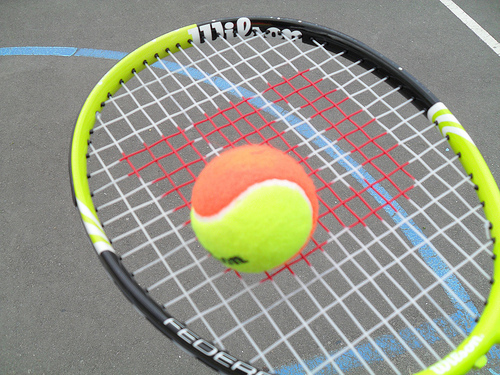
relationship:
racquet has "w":
[71, 17, 496, 371] [125, 70, 419, 289]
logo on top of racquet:
[125, 70, 419, 289] [71, 17, 496, 371]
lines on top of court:
[3, 45, 497, 368] [5, 5, 493, 368]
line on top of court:
[442, 5, 498, 57] [5, 5, 493, 368]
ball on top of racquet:
[190, 144, 321, 276] [71, 17, 496, 371]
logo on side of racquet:
[125, 70, 419, 289] [71, 17, 496, 371]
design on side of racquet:
[66, 200, 117, 255] [71, 17, 496, 371]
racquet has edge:
[71, 17, 496, 371] [32, 28, 193, 254]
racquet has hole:
[71, 17, 496, 371] [149, 47, 166, 63]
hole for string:
[149, 47, 166, 63] [152, 48, 427, 367]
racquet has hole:
[71, 17, 496, 371] [186, 40, 195, 47]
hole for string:
[186, 40, 195, 47] [86, 20, 497, 372]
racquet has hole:
[71, 17, 496, 371] [118, 78, 127, 89]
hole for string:
[118, 78, 127, 89] [86, 20, 497, 372]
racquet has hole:
[71, 17, 496, 371] [84, 174, 94, 182]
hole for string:
[84, 174, 94, 182] [86, 20, 497, 372]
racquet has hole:
[71, 17, 496, 371] [430, 121, 442, 128]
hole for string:
[430, 121, 442, 128] [86, 20, 497, 372]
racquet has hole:
[71, 17, 496, 371] [469, 170, 475, 181]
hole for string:
[469, 170, 475, 181] [86, 20, 497, 372]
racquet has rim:
[71, 17, 496, 371] [72, 18, 495, 370]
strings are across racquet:
[86, 25, 497, 369] [71, 17, 496, 371]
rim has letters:
[72, 18, 495, 370] [185, 22, 303, 47]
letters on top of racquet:
[185, 22, 303, 47] [71, 17, 496, 371]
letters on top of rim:
[185, 22, 303, 47] [72, 18, 495, 370]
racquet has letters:
[71, 17, 496, 371] [185, 22, 303, 47]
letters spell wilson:
[185, 22, 303, 47] [187, 17, 303, 49]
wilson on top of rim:
[187, 17, 303, 49] [72, 18, 495, 370]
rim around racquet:
[72, 18, 495, 370] [71, 17, 496, 371]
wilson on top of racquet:
[187, 17, 303, 49] [71, 17, 496, 371]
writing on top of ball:
[213, 252, 251, 269] [190, 144, 321, 276]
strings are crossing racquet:
[86, 25, 497, 369] [71, 17, 496, 371]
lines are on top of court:
[3, 45, 497, 368] [5, 5, 493, 368]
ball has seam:
[190, 144, 321, 276] [191, 177, 316, 230]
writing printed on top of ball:
[213, 252, 251, 269] [190, 144, 321, 276]